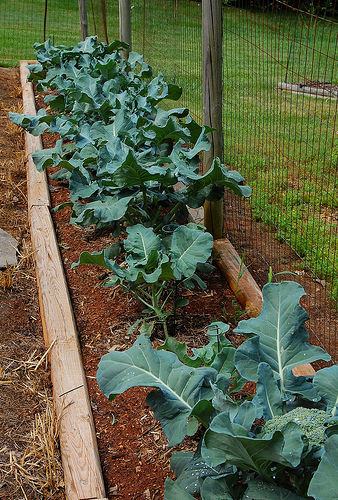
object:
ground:
[1, 0, 337, 498]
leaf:
[96, 332, 236, 447]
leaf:
[170, 224, 214, 281]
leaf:
[123, 223, 166, 267]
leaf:
[70, 249, 128, 279]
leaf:
[173, 155, 252, 209]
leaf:
[75, 196, 135, 229]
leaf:
[105, 148, 177, 188]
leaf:
[96, 138, 139, 178]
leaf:
[173, 114, 217, 160]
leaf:
[31, 138, 77, 173]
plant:
[69, 222, 213, 339]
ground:
[108, 417, 153, 497]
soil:
[1, 137, 14, 155]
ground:
[303, 79, 317, 100]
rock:
[0, 226, 19, 268]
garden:
[0, 0, 338, 499]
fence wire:
[0, 0, 338, 368]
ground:
[115, 400, 155, 458]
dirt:
[72, 272, 91, 293]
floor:
[235, 63, 278, 95]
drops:
[185, 462, 213, 494]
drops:
[312, 397, 318, 401]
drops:
[289, 449, 296, 466]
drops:
[253, 481, 290, 495]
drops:
[120, 369, 134, 382]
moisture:
[282, 321, 318, 402]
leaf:
[232, 278, 331, 419]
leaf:
[175, 436, 241, 499]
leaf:
[200, 399, 305, 484]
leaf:
[240, 473, 298, 498]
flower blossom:
[293, 417, 300, 424]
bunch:
[260, 405, 338, 447]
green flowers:
[9, 36, 338, 499]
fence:
[0, 1, 338, 379]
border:
[19, 60, 109, 499]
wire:
[222, 0, 338, 366]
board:
[201, 1, 227, 239]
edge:
[95, 432, 108, 498]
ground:
[117, 445, 141, 467]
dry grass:
[0, 336, 78, 499]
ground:
[0, 65, 36, 498]